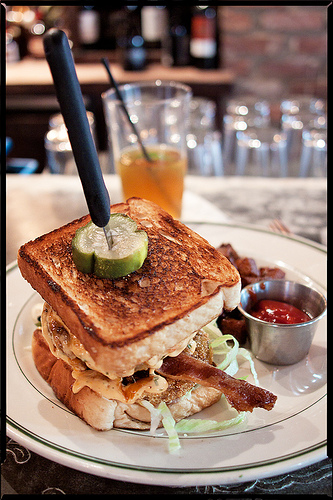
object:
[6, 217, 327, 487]
plate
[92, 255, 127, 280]
green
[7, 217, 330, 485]
lines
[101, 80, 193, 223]
glass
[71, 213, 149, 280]
pickle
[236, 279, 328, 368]
cup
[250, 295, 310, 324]
ketchup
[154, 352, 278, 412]
bacon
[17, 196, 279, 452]
sandwich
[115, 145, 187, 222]
liquid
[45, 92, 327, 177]
glasses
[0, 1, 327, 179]
back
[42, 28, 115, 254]
knife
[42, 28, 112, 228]
handle